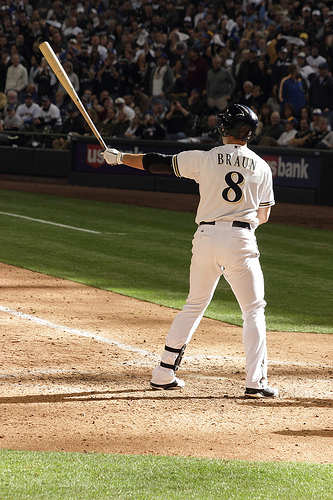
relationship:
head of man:
[214, 97, 269, 142] [169, 102, 282, 404]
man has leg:
[169, 102, 282, 404] [221, 237, 289, 403]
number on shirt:
[219, 166, 254, 206] [179, 129, 327, 146]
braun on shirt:
[215, 147, 270, 173] [179, 129, 327, 146]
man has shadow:
[169, 102, 282, 404] [19, 376, 186, 423]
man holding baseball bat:
[169, 102, 282, 404] [28, 36, 107, 152]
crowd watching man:
[122, 16, 274, 109] [169, 102, 282, 404]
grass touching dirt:
[287, 256, 309, 292] [59, 286, 110, 327]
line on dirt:
[58, 321, 83, 350] [59, 286, 110, 327]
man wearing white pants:
[169, 102, 282, 404] [200, 229, 261, 358]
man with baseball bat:
[169, 102, 282, 404] [28, 36, 107, 152]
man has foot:
[169, 102, 282, 404] [251, 381, 288, 413]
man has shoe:
[169, 102, 282, 404] [230, 377, 292, 398]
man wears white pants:
[169, 102, 282, 404] [200, 229, 261, 358]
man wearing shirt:
[169, 102, 282, 404] [179, 129, 327, 146]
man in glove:
[169, 102, 282, 404] [100, 142, 127, 165]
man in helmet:
[169, 102, 282, 404] [221, 112, 258, 141]